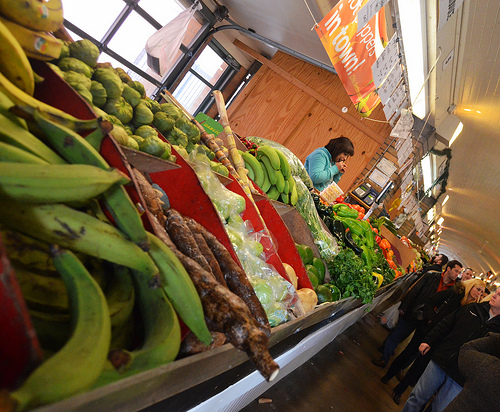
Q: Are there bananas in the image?
A: Yes, there is a banana.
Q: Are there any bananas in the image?
A: Yes, there is a banana.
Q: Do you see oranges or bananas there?
A: Yes, there is a banana.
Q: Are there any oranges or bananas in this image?
A: Yes, there is a banana.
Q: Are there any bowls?
A: No, there are no bowls.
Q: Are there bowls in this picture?
A: No, there are no bowls.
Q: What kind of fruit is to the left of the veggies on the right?
A: The fruit is a banana.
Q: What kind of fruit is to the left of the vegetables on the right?
A: The fruit is a banana.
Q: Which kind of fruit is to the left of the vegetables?
A: The fruit is a banana.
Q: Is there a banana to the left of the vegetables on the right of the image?
A: Yes, there is a banana to the left of the veggies.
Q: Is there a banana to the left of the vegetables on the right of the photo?
A: Yes, there is a banana to the left of the veggies.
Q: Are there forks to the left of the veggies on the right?
A: No, there is a banana to the left of the vegetables.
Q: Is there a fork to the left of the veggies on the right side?
A: No, there is a banana to the left of the vegetables.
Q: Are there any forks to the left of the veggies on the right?
A: No, there is a banana to the left of the vegetables.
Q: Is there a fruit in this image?
A: Yes, there is a fruit.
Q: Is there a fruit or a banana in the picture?
A: Yes, there is a fruit.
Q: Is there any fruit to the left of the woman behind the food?
A: Yes, there is a fruit to the left of the woman.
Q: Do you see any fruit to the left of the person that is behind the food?
A: Yes, there is a fruit to the left of the woman.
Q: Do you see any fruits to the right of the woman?
A: No, the fruit is to the left of the woman.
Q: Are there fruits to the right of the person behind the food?
A: No, the fruit is to the left of the woman.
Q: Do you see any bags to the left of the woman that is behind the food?
A: No, there is a fruit to the left of the woman.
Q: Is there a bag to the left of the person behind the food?
A: No, there is a fruit to the left of the woman.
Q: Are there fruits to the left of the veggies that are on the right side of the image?
A: Yes, there is a fruit to the left of the veggies.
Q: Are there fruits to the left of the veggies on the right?
A: Yes, there is a fruit to the left of the veggies.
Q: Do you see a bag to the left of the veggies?
A: No, there is a fruit to the left of the veggies.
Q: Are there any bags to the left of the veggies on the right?
A: No, there is a fruit to the left of the veggies.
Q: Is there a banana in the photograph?
A: Yes, there is a banana.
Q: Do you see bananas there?
A: Yes, there is a banana.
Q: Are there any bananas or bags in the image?
A: Yes, there is a banana.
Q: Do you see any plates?
A: No, there are no plates.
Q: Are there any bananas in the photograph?
A: Yes, there is a banana.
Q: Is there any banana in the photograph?
A: Yes, there is a banana.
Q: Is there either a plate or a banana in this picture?
A: Yes, there is a banana.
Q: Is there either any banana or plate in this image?
A: Yes, there is a banana.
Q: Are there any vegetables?
A: Yes, there are vegetables.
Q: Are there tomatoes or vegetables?
A: Yes, there are vegetables.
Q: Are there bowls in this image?
A: No, there are no bowls.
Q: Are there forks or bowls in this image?
A: No, there are no bowls or forks.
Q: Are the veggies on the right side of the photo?
A: Yes, the veggies are on the right of the image.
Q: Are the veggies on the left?
A: No, the veggies are on the right of the image.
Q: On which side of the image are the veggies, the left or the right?
A: The veggies are on the right of the image.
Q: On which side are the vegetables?
A: The vegetables are on the right of the image.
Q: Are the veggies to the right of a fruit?
A: Yes, the veggies are to the right of a fruit.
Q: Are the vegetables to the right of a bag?
A: No, the vegetables are to the right of a fruit.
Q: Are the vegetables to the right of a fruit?
A: Yes, the vegetables are to the right of a fruit.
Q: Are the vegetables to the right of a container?
A: No, the vegetables are to the right of a fruit.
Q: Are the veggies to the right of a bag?
A: No, the veggies are to the right of a fruit.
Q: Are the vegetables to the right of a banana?
A: Yes, the vegetables are to the right of a banana.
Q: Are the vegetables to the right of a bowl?
A: No, the vegetables are to the right of a banana.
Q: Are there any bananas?
A: Yes, there is a banana.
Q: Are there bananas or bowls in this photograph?
A: Yes, there is a banana.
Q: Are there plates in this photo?
A: No, there are no plates.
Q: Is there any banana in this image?
A: Yes, there is a banana.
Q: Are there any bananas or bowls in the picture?
A: Yes, there is a banana.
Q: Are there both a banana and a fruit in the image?
A: Yes, there are both a banana and a fruit.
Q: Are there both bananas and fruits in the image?
A: Yes, there are both a banana and a fruit.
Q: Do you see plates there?
A: No, there are no plates.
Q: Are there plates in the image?
A: No, there are no plates.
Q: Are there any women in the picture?
A: Yes, there is a woman.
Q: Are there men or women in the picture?
A: Yes, there is a woman.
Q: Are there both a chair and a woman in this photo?
A: No, there is a woman but no chairs.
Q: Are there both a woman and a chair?
A: No, there is a woman but no chairs.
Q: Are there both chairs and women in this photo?
A: No, there is a woman but no chairs.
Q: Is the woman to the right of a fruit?
A: Yes, the woman is to the right of a fruit.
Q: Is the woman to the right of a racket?
A: No, the woman is to the right of a fruit.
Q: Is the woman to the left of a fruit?
A: No, the woman is to the right of a fruit.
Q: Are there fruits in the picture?
A: Yes, there is a fruit.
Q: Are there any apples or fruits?
A: Yes, there is a fruit.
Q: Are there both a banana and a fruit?
A: Yes, there are both a fruit and a banana.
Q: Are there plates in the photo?
A: No, there are no plates.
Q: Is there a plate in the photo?
A: No, there are no plates.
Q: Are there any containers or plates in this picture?
A: No, there are no plates or containers.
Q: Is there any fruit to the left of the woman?
A: Yes, there is a fruit to the left of the woman.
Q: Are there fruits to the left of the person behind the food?
A: Yes, there is a fruit to the left of the woman.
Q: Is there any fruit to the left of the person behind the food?
A: Yes, there is a fruit to the left of the woman.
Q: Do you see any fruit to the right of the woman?
A: No, the fruit is to the left of the woman.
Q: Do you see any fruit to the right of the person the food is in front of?
A: No, the fruit is to the left of the woman.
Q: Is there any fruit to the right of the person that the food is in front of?
A: No, the fruit is to the left of the woman.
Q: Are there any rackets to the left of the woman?
A: No, there is a fruit to the left of the woman.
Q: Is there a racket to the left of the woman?
A: No, there is a fruit to the left of the woman.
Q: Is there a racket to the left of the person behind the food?
A: No, there is a fruit to the left of the woman.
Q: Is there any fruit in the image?
A: Yes, there is a fruit.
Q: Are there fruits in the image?
A: Yes, there is a fruit.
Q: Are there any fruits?
A: Yes, there is a fruit.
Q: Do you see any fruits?
A: Yes, there is a fruit.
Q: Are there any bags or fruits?
A: Yes, there is a fruit.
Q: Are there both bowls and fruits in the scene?
A: No, there is a fruit but no bowls.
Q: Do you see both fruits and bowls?
A: No, there is a fruit but no bowls.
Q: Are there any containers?
A: No, there are no containers.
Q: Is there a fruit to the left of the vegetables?
A: Yes, there is a fruit to the left of the vegetables.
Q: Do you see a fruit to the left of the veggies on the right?
A: Yes, there is a fruit to the left of the vegetables.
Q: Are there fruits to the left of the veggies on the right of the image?
A: Yes, there is a fruit to the left of the vegetables.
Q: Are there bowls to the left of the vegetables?
A: No, there is a fruit to the left of the vegetables.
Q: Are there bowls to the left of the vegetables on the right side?
A: No, there is a fruit to the left of the vegetables.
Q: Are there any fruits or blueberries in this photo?
A: Yes, there is a fruit.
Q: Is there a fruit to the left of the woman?
A: Yes, there is a fruit to the left of the woman.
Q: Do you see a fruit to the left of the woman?
A: Yes, there is a fruit to the left of the woman.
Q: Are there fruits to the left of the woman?
A: Yes, there is a fruit to the left of the woman.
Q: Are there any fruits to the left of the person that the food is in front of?
A: Yes, there is a fruit to the left of the woman.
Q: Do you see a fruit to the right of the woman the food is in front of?
A: No, the fruit is to the left of the woman.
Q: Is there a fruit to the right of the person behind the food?
A: No, the fruit is to the left of the woman.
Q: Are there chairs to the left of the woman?
A: No, there is a fruit to the left of the woman.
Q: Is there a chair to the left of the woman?
A: No, there is a fruit to the left of the woman.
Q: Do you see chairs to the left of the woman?
A: No, there is a fruit to the left of the woman.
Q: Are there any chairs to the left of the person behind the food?
A: No, there is a fruit to the left of the woman.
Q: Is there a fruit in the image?
A: Yes, there is a fruit.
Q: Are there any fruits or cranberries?
A: Yes, there is a fruit.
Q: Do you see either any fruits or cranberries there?
A: Yes, there is a fruit.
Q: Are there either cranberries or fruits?
A: Yes, there is a fruit.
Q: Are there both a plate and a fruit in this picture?
A: No, there is a fruit but no plates.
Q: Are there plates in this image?
A: No, there are no plates.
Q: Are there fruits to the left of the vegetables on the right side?
A: Yes, there is a fruit to the left of the vegetables.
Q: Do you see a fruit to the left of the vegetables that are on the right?
A: Yes, there is a fruit to the left of the vegetables.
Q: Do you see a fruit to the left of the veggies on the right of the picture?
A: Yes, there is a fruit to the left of the vegetables.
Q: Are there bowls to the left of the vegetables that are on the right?
A: No, there is a fruit to the left of the vegetables.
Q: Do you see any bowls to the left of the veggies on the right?
A: No, there is a fruit to the left of the vegetables.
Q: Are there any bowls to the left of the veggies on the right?
A: No, there is a fruit to the left of the vegetables.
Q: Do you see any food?
A: Yes, there is food.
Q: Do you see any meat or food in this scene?
A: Yes, there is food.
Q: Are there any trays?
A: No, there are no trays.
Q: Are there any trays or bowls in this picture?
A: No, there are no trays or bowls.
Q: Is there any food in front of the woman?
A: Yes, there is food in front of the woman.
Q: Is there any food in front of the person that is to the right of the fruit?
A: Yes, there is food in front of the woman.